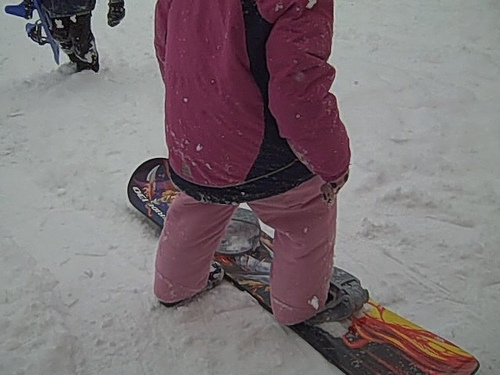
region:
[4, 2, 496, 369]
two people in snow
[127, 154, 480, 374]
snowboard on the ground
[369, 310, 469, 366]
yellow and red design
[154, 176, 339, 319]
pink pants on legs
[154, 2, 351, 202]
pink and black winter coat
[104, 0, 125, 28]
dark mitten on hand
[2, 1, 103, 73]
person holding blue snowbaord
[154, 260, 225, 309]
boot on ground surface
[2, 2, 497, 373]
white snow on ground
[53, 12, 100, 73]
snow on dark pants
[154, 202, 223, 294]
this is a leg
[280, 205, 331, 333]
this is a leg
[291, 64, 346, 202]
this is a hand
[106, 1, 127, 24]
this is a leg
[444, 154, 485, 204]
this is a patch of snow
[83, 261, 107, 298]
this is a patch of snow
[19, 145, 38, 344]
this is a patch of snow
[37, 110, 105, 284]
this is a patch of snow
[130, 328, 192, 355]
this is a patch of snow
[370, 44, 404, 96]
this is a patch of snow